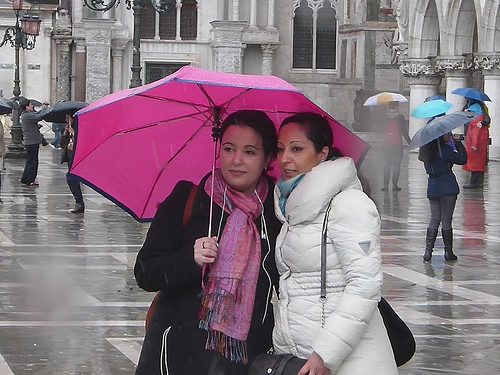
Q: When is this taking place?
A: Daytime.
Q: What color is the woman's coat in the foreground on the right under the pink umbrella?
A: White.